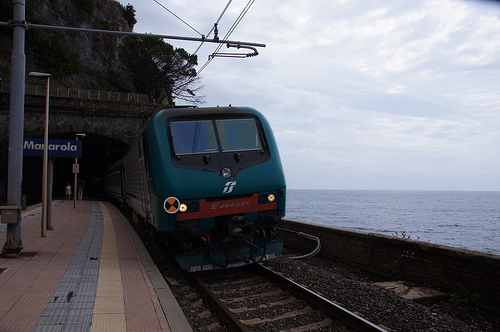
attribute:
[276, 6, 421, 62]
clouds — white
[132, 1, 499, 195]
sky — blue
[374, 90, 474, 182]
clouds — white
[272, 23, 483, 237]
sky — blue